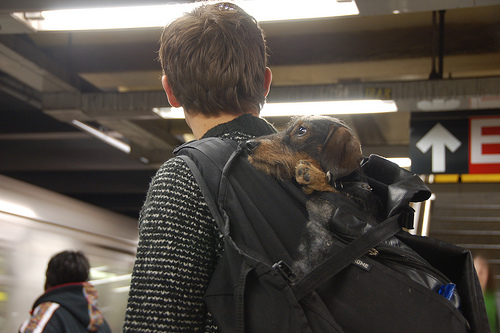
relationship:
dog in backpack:
[259, 119, 308, 167] [304, 188, 458, 316]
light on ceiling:
[38, 14, 151, 64] [52, 37, 145, 176]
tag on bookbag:
[413, 269, 498, 321] [328, 207, 435, 315]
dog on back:
[259, 119, 308, 167] [203, 130, 314, 286]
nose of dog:
[238, 130, 282, 165] [259, 119, 308, 167]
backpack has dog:
[304, 188, 458, 316] [259, 119, 308, 167]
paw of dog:
[306, 149, 324, 197] [259, 119, 308, 167]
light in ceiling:
[38, 14, 151, 64] [52, 37, 145, 176]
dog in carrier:
[259, 119, 308, 167] [270, 165, 414, 253]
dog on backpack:
[259, 119, 308, 167] [304, 188, 458, 316]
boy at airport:
[149, 30, 288, 230] [53, 38, 462, 310]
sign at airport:
[397, 101, 498, 195] [53, 38, 462, 310]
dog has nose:
[259, 119, 308, 167] [238, 130, 282, 165]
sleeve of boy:
[131, 197, 196, 290] [149, 30, 288, 230]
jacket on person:
[34, 277, 75, 332] [28, 232, 119, 327]